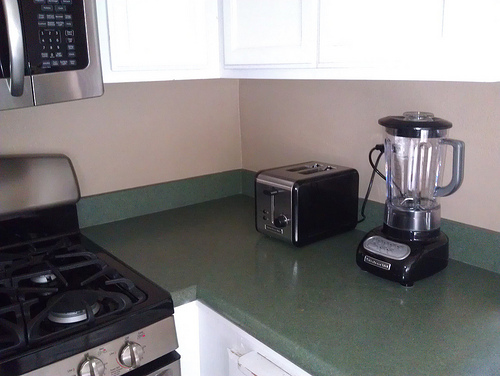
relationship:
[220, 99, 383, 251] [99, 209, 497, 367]
toaster on counter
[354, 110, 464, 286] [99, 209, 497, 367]
appliance on counter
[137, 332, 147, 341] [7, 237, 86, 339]
light on burner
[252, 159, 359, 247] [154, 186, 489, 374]
appliance on counter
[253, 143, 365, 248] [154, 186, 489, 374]
appliance on counter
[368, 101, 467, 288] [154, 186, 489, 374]
appliance on counter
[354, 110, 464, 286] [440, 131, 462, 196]
appliance has handle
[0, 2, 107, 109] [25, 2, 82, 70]
microwave has control pad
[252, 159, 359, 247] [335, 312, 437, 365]
appliance on counter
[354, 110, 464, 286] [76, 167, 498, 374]
appliance on counter